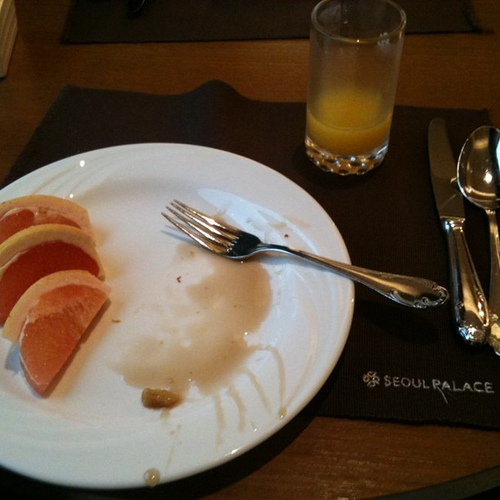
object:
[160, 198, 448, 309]
fork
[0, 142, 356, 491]
plate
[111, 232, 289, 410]
crumbs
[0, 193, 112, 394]
grapefruit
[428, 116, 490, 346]
knife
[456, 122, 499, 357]
spoon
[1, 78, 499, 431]
placemat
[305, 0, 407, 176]
glass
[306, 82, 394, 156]
orange juice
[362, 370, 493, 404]
insignia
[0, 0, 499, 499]
table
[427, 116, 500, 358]
silverware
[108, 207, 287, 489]
syrup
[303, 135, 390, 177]
bottom